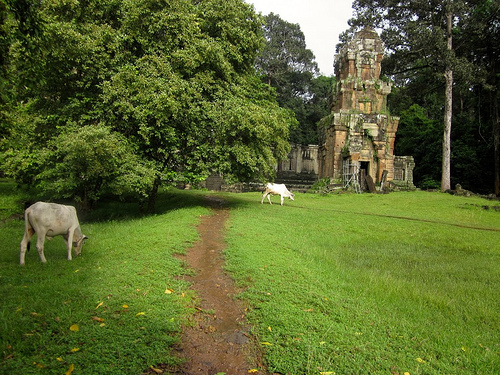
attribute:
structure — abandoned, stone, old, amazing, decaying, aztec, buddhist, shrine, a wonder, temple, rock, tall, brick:
[193, 20, 418, 198]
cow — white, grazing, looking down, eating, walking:
[16, 200, 89, 268]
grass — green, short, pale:
[1, 179, 499, 374]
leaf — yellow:
[163, 285, 174, 301]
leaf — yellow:
[67, 323, 83, 334]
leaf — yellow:
[68, 345, 85, 356]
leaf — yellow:
[63, 360, 76, 374]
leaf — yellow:
[122, 302, 133, 313]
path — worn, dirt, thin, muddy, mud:
[154, 191, 274, 374]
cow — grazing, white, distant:
[260, 184, 295, 209]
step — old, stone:
[289, 187, 322, 197]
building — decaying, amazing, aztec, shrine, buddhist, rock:
[276, 139, 321, 175]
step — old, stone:
[282, 181, 317, 190]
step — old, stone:
[276, 177, 316, 186]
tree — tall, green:
[359, 2, 497, 199]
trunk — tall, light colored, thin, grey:
[439, 9, 455, 197]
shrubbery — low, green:
[306, 176, 354, 199]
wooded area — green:
[292, 2, 499, 197]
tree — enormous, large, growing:
[0, 0, 300, 207]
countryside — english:
[0, 1, 499, 375]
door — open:
[358, 156, 370, 191]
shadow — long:
[218, 196, 499, 234]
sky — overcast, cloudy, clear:
[235, 0, 499, 100]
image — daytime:
[0, 2, 496, 374]